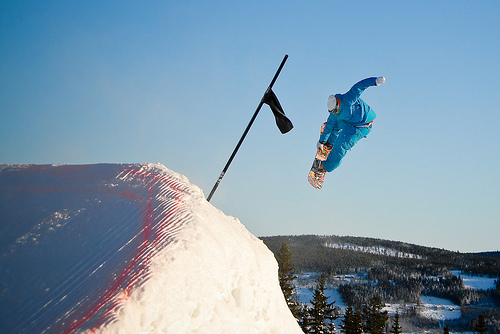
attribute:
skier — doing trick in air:
[305, 75, 389, 193]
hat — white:
[320, 91, 337, 113]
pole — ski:
[203, 45, 303, 222]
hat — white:
[325, 91, 339, 113]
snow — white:
[197, 226, 223, 253]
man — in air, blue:
[309, 75, 384, 187]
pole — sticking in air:
[209, 40, 297, 204]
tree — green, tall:
[267, 237, 302, 322]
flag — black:
[201, 52, 296, 203]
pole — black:
[217, 56, 292, 205]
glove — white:
[369, 76, 394, 93]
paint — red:
[16, 167, 181, 332]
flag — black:
[261, 88, 298, 140]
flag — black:
[262, 87, 290, 133]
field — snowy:
[4, 154, 323, 332]